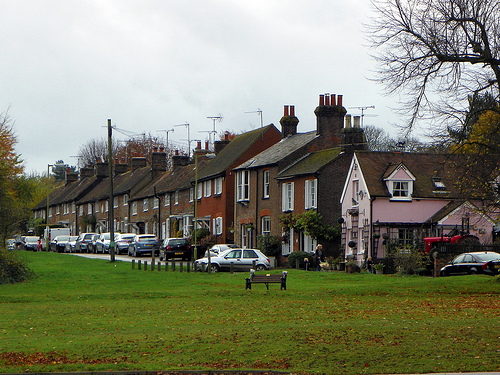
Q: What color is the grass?
A: Green.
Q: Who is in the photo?
A: No one.